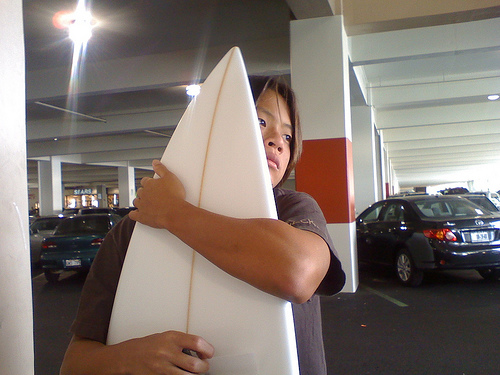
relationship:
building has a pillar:
[1, 2, 499, 374] [289, 14, 360, 294]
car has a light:
[357, 195, 499, 285] [425, 229, 457, 242]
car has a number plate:
[357, 195, 499, 285] [470, 230, 488, 245]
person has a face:
[55, 77, 344, 374] [256, 86, 290, 190]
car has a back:
[357, 195, 499, 285] [408, 197, 499, 273]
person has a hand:
[55, 77, 344, 374] [129, 160, 184, 227]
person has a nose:
[55, 77, 344, 374] [267, 126, 283, 149]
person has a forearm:
[55, 77, 344, 374] [168, 203, 301, 301]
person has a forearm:
[55, 77, 344, 374] [74, 330, 158, 374]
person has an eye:
[55, 77, 344, 374] [258, 117, 265, 127]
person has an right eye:
[55, 77, 344, 374] [281, 132, 290, 141]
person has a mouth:
[55, 77, 344, 374] [266, 153, 281, 169]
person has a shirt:
[55, 77, 344, 374] [272, 187, 345, 299]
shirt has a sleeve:
[272, 187, 345, 299] [72, 209, 136, 340]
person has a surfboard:
[55, 77, 344, 374] [106, 43, 301, 374]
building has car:
[1, 2, 499, 374] [357, 195, 499, 285]